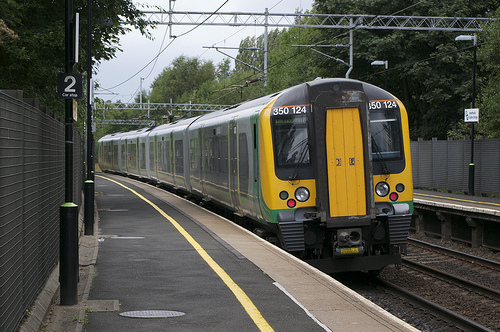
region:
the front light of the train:
[279, 190, 288, 200]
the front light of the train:
[287, 196, 295, 207]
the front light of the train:
[293, 184, 309, 202]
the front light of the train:
[375, 180, 388, 196]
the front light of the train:
[397, 180, 404, 194]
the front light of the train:
[390, 191, 395, 200]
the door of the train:
[326, 106, 366, 216]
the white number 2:
[295, 105, 301, 113]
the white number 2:
[386, 97, 391, 108]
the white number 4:
[301, 105, 306, 112]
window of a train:
[255, 101, 328, 177]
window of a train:
[356, 97, 401, 169]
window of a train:
[208, 128, 225, 169]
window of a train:
[194, 133, 216, 180]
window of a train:
[183, 126, 206, 182]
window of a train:
[145, 126, 175, 181]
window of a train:
[125, 130, 150, 166]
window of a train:
[119, 135, 131, 159]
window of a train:
[109, 135, 125, 164]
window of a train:
[104, 142, 117, 164]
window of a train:
[221, 126, 255, 188]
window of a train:
[213, 133, 234, 180]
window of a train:
[170, 138, 182, 172]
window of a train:
[121, 135, 138, 173]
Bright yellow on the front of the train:
[256, 75, 417, 210]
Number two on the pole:
[59, 73, 82, 100]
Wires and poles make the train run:
[84, 1, 499, 139]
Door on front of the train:
[321, 104, 372, 219]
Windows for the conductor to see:
[267, 106, 408, 168]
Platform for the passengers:
[84, 166, 416, 330]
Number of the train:
[269, 98, 398, 115]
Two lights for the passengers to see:
[362, 33, 481, 198]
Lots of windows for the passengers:
[95, 131, 252, 181]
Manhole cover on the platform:
[115, 306, 187, 321]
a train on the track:
[182, 57, 424, 266]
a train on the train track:
[239, 54, 476, 326]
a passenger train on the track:
[171, 61, 450, 300]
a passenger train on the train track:
[139, 86, 438, 306]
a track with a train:
[189, 50, 435, 328]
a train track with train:
[199, 68, 499, 320]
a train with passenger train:
[127, 38, 479, 325]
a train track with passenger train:
[141, 70, 457, 325]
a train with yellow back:
[203, 82, 493, 278]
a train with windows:
[214, 78, 489, 330]